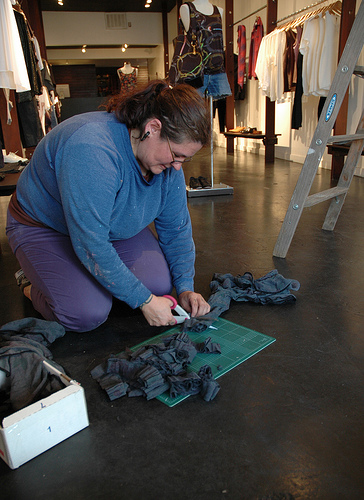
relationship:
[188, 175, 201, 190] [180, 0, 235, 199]
shoe beside mannequin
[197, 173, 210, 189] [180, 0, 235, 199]
shoe beside mannequin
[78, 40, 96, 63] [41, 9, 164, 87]
light on wall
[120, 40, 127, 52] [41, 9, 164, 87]
light on wall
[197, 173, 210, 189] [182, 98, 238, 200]
shoe on stand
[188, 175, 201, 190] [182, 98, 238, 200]
shoe on stand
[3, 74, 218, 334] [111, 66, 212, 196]
lady has head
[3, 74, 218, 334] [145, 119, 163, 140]
lady has ear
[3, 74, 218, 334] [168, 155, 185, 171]
lady has nose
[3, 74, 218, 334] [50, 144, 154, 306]
lady has arm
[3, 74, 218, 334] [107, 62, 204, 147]
lady has hair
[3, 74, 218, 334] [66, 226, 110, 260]
lady has elbow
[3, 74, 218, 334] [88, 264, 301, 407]
lady cutting fabric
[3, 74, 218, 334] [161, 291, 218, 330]
lady cutting with scissors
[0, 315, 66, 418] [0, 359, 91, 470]
material in box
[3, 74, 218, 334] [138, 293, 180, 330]
lady has hand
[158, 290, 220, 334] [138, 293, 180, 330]
scissors in hand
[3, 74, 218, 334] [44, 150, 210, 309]
lady has sleeve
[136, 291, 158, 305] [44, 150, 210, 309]
tattoo peeking from under sleeve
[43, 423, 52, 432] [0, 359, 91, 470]
number printed on box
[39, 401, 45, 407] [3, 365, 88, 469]
seven printed on box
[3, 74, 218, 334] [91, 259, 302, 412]
lady cuts material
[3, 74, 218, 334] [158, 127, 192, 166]
lady wears glasses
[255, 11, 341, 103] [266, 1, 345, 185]
clothes on rack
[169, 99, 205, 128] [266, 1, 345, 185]
wall has rack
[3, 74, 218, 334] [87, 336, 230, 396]
lady cuts fabric pieces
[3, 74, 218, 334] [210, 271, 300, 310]
lady cuts fabric pieces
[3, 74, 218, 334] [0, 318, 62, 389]
lady cuts fabric pieces